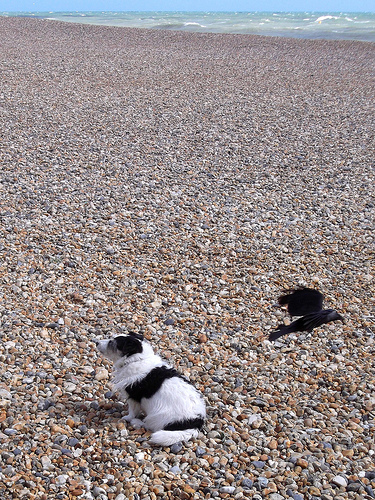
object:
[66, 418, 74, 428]
shadow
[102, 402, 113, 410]
rock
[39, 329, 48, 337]
rock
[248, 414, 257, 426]
rock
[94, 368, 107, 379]
rock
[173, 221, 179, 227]
rock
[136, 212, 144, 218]
stones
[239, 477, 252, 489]
rock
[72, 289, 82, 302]
stones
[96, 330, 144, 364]
head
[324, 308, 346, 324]
head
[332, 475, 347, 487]
rock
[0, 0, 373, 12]
sky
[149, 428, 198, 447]
tail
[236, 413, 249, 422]
rock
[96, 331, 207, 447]
dog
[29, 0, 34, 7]
clouds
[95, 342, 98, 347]
nose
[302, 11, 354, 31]
wave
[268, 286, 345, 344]
bird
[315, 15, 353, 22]
cap wave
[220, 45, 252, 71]
ground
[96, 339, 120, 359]
face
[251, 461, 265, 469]
rock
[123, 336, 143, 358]
ear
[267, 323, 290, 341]
tail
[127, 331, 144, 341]
ears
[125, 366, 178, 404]
stripe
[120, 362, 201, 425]
back